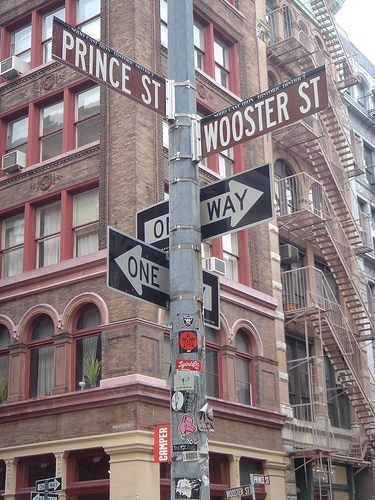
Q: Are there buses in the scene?
A: No, there are no buses.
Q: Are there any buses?
A: No, there are no buses.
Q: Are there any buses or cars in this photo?
A: No, there are no buses or cars.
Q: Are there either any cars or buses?
A: No, there are no buses or cars.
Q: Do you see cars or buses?
A: No, there are no buses or cars.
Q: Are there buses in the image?
A: No, there are no buses.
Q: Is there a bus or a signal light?
A: No, there are no buses or traffic lights.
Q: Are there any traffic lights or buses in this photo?
A: No, there are no buses or traffic lights.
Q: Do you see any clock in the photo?
A: No, there are no clocks.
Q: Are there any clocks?
A: No, there are no clocks.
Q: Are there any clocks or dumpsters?
A: No, there are no clocks or dumpsters.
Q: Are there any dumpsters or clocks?
A: No, there are no clocks or dumpsters.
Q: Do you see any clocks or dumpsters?
A: No, there are no clocks or dumpsters.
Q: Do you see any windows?
A: Yes, there is a window.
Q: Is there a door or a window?
A: Yes, there is a window.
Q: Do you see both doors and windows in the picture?
A: No, there is a window but no doors.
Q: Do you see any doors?
A: No, there are no doors.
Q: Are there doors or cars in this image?
A: No, there are no doors or cars.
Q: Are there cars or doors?
A: No, there are no doors or cars.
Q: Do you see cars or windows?
A: Yes, there is a window.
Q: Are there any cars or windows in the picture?
A: Yes, there is a window.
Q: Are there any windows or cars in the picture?
A: Yes, there is a window.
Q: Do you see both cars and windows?
A: No, there is a window but no cars.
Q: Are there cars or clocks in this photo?
A: No, there are no clocks or cars.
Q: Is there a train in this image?
A: No, there are no trains.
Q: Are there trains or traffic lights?
A: No, there are no trains or traffic lights.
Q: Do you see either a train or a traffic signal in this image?
A: No, there are no trains or traffic lights.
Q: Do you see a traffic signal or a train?
A: No, there are no trains or traffic lights.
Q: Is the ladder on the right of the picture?
A: Yes, the ladder is on the right of the image.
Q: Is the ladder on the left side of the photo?
A: No, the ladder is on the right of the image.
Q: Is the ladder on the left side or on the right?
A: The ladder is on the right of the image.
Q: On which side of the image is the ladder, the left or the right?
A: The ladder is on the right of the image.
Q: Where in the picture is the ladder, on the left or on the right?
A: The ladder is on the right of the image.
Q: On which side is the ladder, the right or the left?
A: The ladder is on the right of the image.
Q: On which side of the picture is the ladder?
A: The ladder is on the right of the image.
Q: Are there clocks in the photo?
A: No, there are no clocks.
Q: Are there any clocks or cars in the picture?
A: No, there are no clocks or cars.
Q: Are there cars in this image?
A: No, there are no cars.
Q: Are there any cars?
A: No, there are no cars.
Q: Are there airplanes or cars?
A: No, there are no cars or airplanes.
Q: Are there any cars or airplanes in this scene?
A: No, there are no cars or airplanes.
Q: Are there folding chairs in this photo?
A: No, there are no folding chairs.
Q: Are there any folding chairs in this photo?
A: No, there are no folding chairs.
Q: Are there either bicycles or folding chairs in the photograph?
A: No, there are no folding chairs or bicycles.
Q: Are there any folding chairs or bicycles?
A: No, there are no folding chairs or bicycles.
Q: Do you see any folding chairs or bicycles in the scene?
A: No, there are no folding chairs or bicycles.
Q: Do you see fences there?
A: No, there are no fences.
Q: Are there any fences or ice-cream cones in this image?
A: No, there are no fences or ice-cream cones.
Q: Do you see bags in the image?
A: No, there are no bags.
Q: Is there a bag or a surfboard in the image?
A: No, there are no bags or surfboards.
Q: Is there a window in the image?
A: Yes, there is a window.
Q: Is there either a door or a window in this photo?
A: Yes, there is a window.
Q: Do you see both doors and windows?
A: No, there is a window but no doors.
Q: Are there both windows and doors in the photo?
A: No, there is a window but no doors.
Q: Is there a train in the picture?
A: No, there are no trains.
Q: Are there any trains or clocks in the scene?
A: No, there are no trains or clocks.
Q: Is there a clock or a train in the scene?
A: No, there are no trains or clocks.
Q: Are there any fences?
A: No, there are no fences.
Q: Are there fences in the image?
A: No, there are no fences.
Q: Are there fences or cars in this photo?
A: No, there are no fences or cars.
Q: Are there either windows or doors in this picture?
A: Yes, there is a window.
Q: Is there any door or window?
A: Yes, there is a window.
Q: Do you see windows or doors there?
A: Yes, there is a window.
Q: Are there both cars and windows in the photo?
A: No, there is a window but no cars.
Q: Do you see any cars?
A: No, there are no cars.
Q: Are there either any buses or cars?
A: No, there are no cars or buses.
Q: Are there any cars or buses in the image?
A: No, there are no cars or buses.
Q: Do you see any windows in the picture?
A: Yes, there is a window.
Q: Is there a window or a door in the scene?
A: Yes, there is a window.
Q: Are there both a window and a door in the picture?
A: No, there is a window but no doors.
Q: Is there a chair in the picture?
A: No, there are no chairs.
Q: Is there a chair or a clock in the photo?
A: No, there are no chairs or clocks.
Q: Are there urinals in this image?
A: No, there are no urinals.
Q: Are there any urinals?
A: No, there are no urinals.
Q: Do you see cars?
A: No, there are no cars.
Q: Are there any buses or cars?
A: No, there are no cars or buses.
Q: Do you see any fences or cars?
A: No, there are no cars or fences.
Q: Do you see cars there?
A: No, there are no cars.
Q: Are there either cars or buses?
A: No, there are no cars or buses.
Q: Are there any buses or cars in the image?
A: No, there are no cars or buses.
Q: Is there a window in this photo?
A: Yes, there is a window.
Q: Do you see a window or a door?
A: Yes, there is a window.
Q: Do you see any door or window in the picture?
A: Yes, there is a window.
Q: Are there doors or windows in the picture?
A: Yes, there is a window.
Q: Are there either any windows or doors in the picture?
A: Yes, there is a window.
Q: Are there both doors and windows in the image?
A: No, there is a window but no doors.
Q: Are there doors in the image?
A: No, there are no doors.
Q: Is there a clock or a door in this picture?
A: No, there are no doors or clocks.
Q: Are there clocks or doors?
A: No, there are no doors or clocks.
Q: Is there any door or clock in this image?
A: No, there are no doors or clocks.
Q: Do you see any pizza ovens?
A: No, there are no pizza ovens.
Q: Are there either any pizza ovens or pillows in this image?
A: No, there are no pizza ovens or pillows.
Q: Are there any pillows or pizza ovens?
A: No, there are no pizza ovens or pillows.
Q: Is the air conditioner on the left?
A: Yes, the air conditioner is on the left of the image.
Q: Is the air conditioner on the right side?
A: No, the air conditioner is on the left of the image.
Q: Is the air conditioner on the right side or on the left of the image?
A: The air conditioner is on the left of the image.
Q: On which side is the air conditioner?
A: The air conditioner is on the left of the image.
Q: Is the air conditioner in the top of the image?
A: Yes, the air conditioner is in the top of the image.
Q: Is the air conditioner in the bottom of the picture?
A: No, the air conditioner is in the top of the image.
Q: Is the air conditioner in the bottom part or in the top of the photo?
A: The air conditioner is in the top of the image.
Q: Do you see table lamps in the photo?
A: No, there are no table lamps.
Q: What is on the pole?
A: The sticker is on the pole.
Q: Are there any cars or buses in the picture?
A: No, there are no cars or buses.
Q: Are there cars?
A: No, there are no cars.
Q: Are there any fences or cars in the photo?
A: No, there are no cars or fences.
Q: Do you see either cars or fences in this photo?
A: No, there are no cars or fences.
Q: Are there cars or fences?
A: No, there are no cars or fences.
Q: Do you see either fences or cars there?
A: No, there are no cars or fences.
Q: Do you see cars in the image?
A: No, there are no cars.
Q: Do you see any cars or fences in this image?
A: No, there are no cars or fences.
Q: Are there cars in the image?
A: No, there are no cars.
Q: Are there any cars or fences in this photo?
A: No, there are no cars or fences.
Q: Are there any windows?
A: Yes, there is a window.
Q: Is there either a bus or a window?
A: Yes, there is a window.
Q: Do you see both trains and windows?
A: No, there is a window but no trains.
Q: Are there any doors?
A: No, there are no doors.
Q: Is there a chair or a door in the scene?
A: No, there are no doors or chairs.